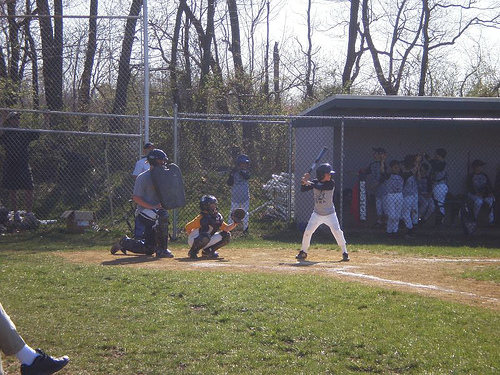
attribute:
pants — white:
[298, 211, 348, 256]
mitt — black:
[227, 207, 252, 227]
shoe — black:
[18, 348, 69, 374]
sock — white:
[14, 343, 41, 370]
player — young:
[290, 162, 354, 265]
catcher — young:
[181, 191, 243, 258]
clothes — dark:
[0, 125, 44, 194]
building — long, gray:
[291, 90, 499, 236]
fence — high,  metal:
[2, 102, 499, 239]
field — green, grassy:
[3, 233, 498, 371]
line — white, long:
[332, 266, 479, 298]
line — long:
[336, 254, 497, 269]